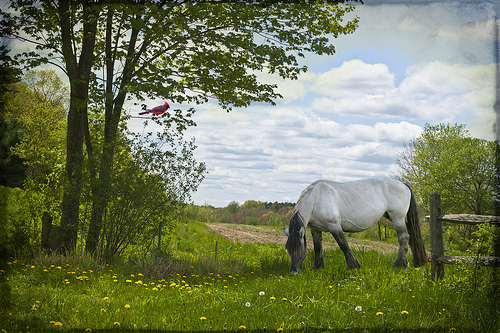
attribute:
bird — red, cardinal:
[139, 101, 173, 115]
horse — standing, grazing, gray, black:
[282, 175, 427, 275]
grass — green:
[1, 217, 499, 331]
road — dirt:
[206, 222, 398, 254]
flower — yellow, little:
[198, 312, 207, 320]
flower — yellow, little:
[53, 319, 62, 326]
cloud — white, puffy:
[306, 58, 397, 95]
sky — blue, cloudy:
[1, 1, 499, 202]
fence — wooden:
[422, 189, 500, 283]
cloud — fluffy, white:
[308, 95, 444, 119]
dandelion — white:
[257, 289, 266, 298]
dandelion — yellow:
[269, 295, 276, 301]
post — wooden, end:
[427, 191, 446, 280]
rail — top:
[424, 212, 499, 225]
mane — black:
[287, 212, 301, 250]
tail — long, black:
[406, 180, 428, 266]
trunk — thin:
[84, 85, 124, 258]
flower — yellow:
[123, 303, 131, 309]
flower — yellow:
[374, 307, 383, 318]